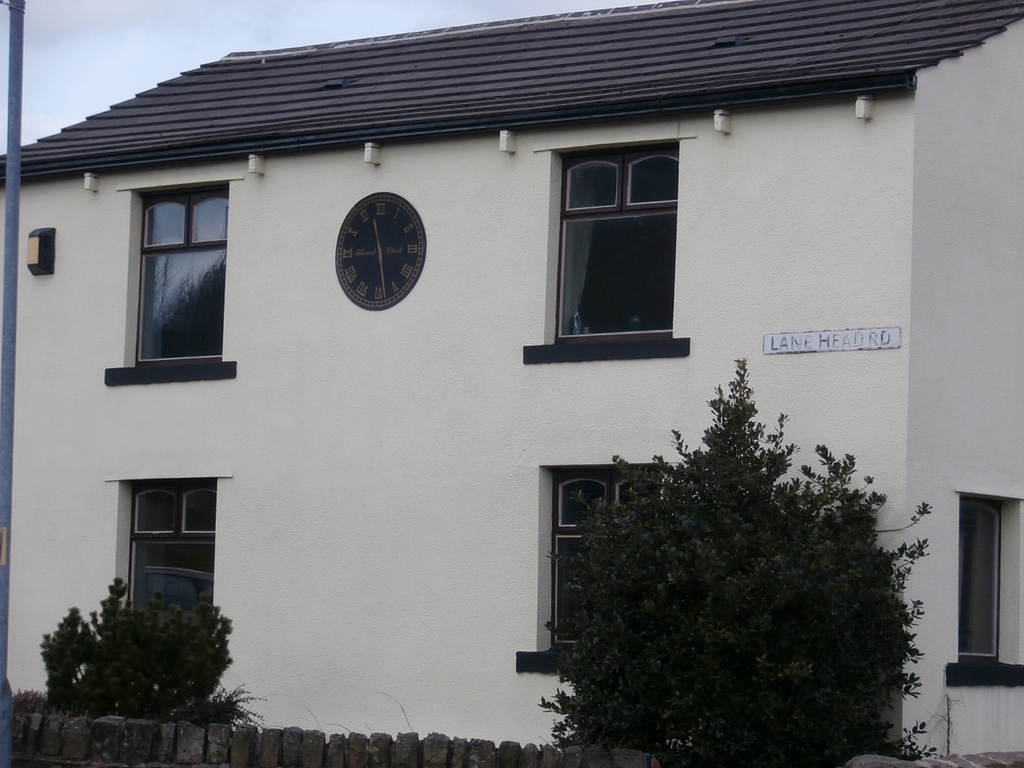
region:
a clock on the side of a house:
[336, 190, 428, 308]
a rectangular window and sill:
[523, 138, 689, 363]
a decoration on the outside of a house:
[26, 225, 56, 277]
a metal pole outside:
[0, 2, 26, 762]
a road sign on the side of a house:
[760, 328, 904, 355]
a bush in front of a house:
[42, 569, 267, 725]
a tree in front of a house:
[535, 360, 940, 765]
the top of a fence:
[4, 710, 804, 764]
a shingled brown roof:
[1, 0, 1020, 191]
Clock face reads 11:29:
[333, 190, 431, 318]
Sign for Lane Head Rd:
[757, 322, 907, 355]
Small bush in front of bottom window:
[36, 583, 243, 724]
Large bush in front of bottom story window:
[552, 373, 929, 756]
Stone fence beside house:
[8, 705, 689, 763]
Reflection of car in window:
[114, 554, 222, 631]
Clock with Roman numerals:
[332, 187, 427, 317]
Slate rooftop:
[11, 0, 1017, 188]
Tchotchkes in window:
[557, 304, 655, 336]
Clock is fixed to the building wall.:
[335, 195, 447, 309]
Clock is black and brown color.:
[315, 178, 434, 315]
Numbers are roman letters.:
[316, 189, 430, 313]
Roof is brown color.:
[142, 43, 737, 124]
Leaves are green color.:
[591, 504, 848, 738]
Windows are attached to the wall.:
[78, 182, 731, 689]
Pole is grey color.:
[5, 12, 28, 358]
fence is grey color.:
[40, 706, 467, 767]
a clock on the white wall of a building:
[0, 96, 912, 744]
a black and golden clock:
[332, 195, 425, 312]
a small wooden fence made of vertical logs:
[14, 712, 659, 766]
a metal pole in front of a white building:
[2, 0, 1018, 759]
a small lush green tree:
[536, 353, 933, 766]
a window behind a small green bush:
[42, 479, 233, 714]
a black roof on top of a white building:
[11, 0, 1020, 751]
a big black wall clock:
[324, 189, 438, 322]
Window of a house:
[549, 145, 676, 339]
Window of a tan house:
[550, 145, 684, 341]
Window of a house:
[544, 461, 661, 658]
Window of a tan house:
[550, 465, 661, 665]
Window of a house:
[950, 497, 1005, 675]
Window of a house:
[117, 181, 236, 365]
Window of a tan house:
[120, 192, 237, 373]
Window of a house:
[97, 454, 235, 660]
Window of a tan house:
[97, 470, 237, 670]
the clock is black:
[332, 197, 431, 308]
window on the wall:
[551, 467, 663, 661]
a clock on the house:
[328, 189, 440, 310]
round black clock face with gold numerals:
[332, 188, 430, 312]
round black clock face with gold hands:
[334, 186, 430, 313]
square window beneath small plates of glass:
[519, 129, 694, 363]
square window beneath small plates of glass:
[100, 175, 238, 391]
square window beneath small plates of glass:
[101, 473, 225, 635]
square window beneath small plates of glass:
[511, 463, 655, 675]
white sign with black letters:
[764, 325, 905, 352]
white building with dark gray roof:
[3, 2, 1021, 184]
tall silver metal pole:
[0, 2, 27, 764]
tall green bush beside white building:
[547, 356, 946, 767]